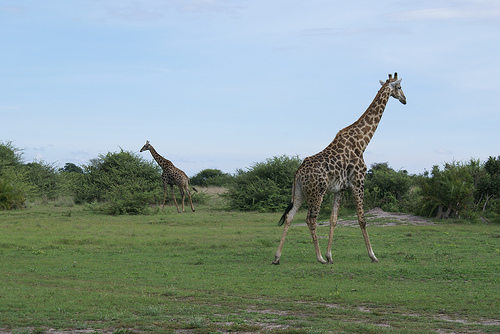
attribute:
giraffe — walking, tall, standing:
[267, 73, 411, 267]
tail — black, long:
[279, 184, 296, 228]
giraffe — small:
[141, 139, 197, 214]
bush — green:
[86, 151, 155, 220]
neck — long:
[342, 95, 392, 148]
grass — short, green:
[68, 212, 255, 276]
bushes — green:
[232, 158, 498, 214]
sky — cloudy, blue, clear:
[11, 0, 498, 155]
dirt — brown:
[368, 206, 416, 226]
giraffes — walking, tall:
[142, 74, 405, 270]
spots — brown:
[328, 141, 356, 186]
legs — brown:
[265, 186, 375, 272]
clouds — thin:
[193, 5, 491, 65]